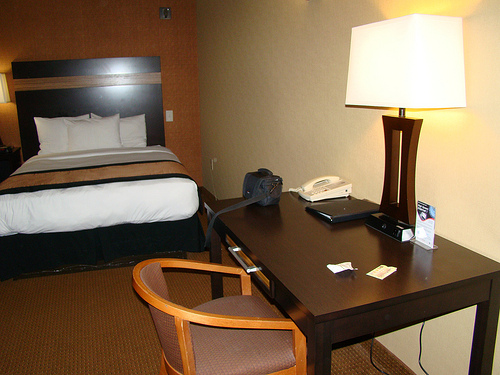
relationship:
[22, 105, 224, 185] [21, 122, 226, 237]
pillows stacked on bed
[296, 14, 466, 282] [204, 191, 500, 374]
display on nightstand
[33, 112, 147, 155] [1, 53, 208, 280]
pillows on bed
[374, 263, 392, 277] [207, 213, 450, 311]
notebook on table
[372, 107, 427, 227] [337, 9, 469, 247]
base of lamp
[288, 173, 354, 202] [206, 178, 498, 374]
phone on table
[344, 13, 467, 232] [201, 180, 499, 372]
display on nightstand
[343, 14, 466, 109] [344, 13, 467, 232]
white lampshade on display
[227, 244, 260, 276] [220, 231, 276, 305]
handle of drawer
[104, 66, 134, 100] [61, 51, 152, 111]
light reflecting on headboard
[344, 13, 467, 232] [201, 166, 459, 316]
display on table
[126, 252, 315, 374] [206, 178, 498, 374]
chair under table